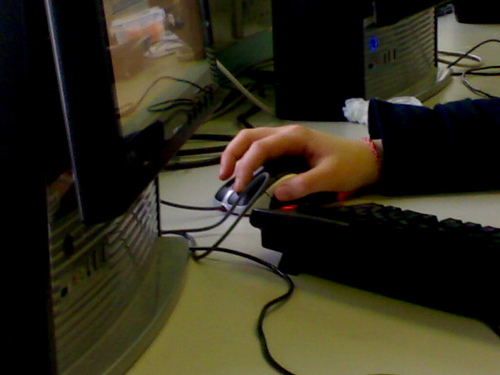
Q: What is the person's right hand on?
A: A mouse.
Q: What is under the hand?
A: Mouse.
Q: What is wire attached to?
A: The mouse.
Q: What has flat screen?
A: Computer monitor.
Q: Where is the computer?
A: On the desk.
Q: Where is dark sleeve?
A: On person's arm.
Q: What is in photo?
A: Monitor on desk.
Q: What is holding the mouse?
A: A hand.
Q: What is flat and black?
A: Keyboard.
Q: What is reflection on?
A: Monitor.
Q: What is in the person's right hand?
A: A mouse.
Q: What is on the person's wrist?
A: A bracelet.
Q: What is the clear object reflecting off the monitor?
A: A storage bin.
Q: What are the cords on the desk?
A: Power cords.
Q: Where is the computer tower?
A: On the right side of the desk.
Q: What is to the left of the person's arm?
A: A keyboard.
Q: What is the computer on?
A: A desk.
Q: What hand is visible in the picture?
A: The person's right hand.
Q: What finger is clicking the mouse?
A: The right pointer finger.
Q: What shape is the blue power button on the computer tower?
A: Circle.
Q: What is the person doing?
A: Holding mouse.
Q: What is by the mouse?
A: Keyboard.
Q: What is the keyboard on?
A: Desk.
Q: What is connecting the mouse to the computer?
A: Wire.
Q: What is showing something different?
A: Reflection on screen.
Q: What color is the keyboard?
A: Black.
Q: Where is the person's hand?
A: On the mouse.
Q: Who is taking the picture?
A: A photographer.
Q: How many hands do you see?
A: One.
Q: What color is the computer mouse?
A: Black and silver.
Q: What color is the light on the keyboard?
A: Red.